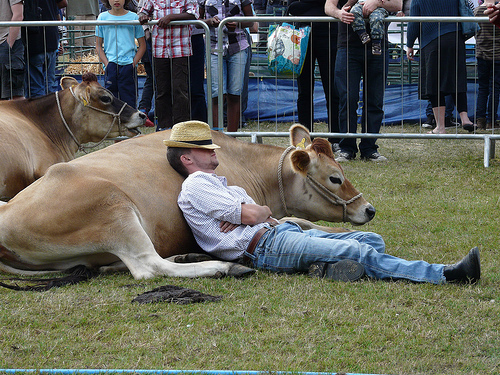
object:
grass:
[0, 132, 497, 374]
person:
[286, 1, 342, 156]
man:
[323, 0, 389, 164]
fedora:
[162, 118, 221, 150]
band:
[161, 136, 222, 151]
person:
[137, 0, 200, 130]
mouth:
[108, 104, 156, 139]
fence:
[209, 5, 494, 168]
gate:
[212, 4, 498, 163]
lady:
[407, 0, 479, 134]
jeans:
[258, 219, 445, 291]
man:
[288, 0, 340, 150]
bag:
[265, 20, 310, 78]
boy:
[84, 1, 149, 122]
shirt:
[89, 7, 150, 68]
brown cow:
[0, 71, 153, 203]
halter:
[51, 87, 126, 148]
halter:
[274, 140, 361, 220]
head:
[277, 121, 379, 228]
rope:
[267, 139, 294, 215]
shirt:
[175, 173, 268, 262]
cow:
[0, 123, 377, 290]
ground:
[0, 119, 497, 374]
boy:
[349, 0, 389, 54]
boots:
[440, 247, 484, 291]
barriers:
[2, 13, 493, 166]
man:
[165, 120, 483, 285]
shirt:
[407, 0, 466, 51]